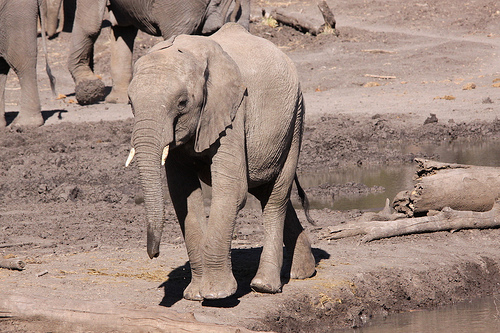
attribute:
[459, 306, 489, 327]
ripple — small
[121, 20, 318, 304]
elephant — baby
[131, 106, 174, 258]
trunk — wet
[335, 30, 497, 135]
dirt — orange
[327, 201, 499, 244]
trunk — tree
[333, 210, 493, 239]
logs — wooden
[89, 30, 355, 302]
elephant — small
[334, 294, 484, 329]
water — muddy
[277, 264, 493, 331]
hole — dirt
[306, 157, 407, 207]
water — muddy